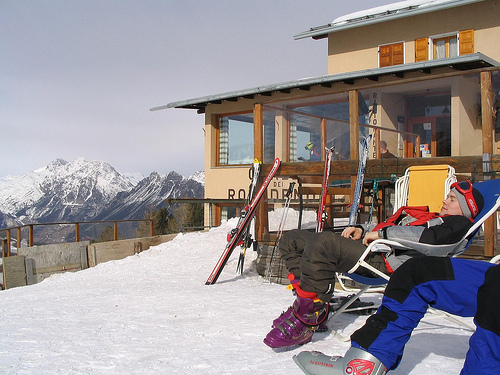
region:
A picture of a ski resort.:
[23, 20, 499, 360]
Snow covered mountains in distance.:
[6, 137, 186, 223]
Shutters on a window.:
[408, 27, 484, 59]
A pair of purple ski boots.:
[258, 282, 333, 352]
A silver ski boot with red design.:
[298, 332, 393, 373]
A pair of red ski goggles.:
[445, 169, 482, 216]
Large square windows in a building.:
[209, 80, 463, 167]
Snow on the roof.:
[313, 4, 437, 26]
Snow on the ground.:
[48, 277, 235, 368]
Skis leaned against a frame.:
[201, 147, 268, 292]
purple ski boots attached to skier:
[228, 292, 353, 351]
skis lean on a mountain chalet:
[192, 162, 284, 294]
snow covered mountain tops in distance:
[35, 146, 114, 202]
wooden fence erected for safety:
[69, 205, 168, 242]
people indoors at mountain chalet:
[267, 84, 369, 176]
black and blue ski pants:
[347, 251, 492, 347]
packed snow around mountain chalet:
[125, 281, 297, 335]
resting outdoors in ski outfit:
[335, 178, 490, 286]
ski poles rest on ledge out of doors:
[263, 179, 299, 285]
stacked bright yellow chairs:
[390, 152, 464, 216]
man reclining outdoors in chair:
[245, 171, 495, 351]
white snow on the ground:
[45, 275, 200, 370]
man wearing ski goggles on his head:
[440, 175, 480, 220]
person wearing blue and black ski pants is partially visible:
[290, 255, 490, 370]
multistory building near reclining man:
[150, 0, 495, 250]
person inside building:
[360, 115, 425, 160]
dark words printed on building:
[210, 160, 330, 205]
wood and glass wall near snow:
[5, 215, 205, 295]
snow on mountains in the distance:
[0, 150, 203, 230]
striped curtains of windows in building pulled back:
[207, 96, 310, 171]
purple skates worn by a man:
[263, 288, 347, 355]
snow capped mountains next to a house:
[14, 151, 113, 208]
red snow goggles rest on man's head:
[446, 180, 486, 221]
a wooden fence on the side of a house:
[18, 219, 157, 240]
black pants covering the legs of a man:
[280, 183, 361, 330]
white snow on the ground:
[93, 262, 229, 344]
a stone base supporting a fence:
[19, 243, 114, 273]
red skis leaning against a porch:
[207, 155, 277, 285]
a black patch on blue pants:
[384, 256, 454, 305]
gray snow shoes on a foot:
[302, 351, 391, 374]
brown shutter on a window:
[452, 25, 478, 58]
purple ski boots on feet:
[255, 267, 339, 359]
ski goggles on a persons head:
[450, 177, 484, 221]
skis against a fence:
[305, 140, 341, 237]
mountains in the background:
[18, 137, 151, 259]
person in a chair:
[248, 162, 498, 367]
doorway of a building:
[395, 107, 462, 165]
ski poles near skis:
[243, 177, 305, 292]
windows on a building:
[426, 29, 463, 59]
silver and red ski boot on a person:
[284, 329, 414, 374]